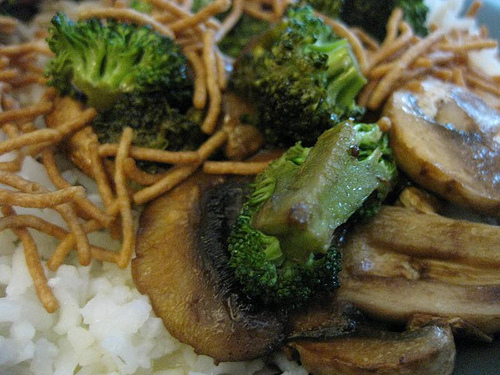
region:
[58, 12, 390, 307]
Broccoli florets on rice.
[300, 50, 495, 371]
Sauteed mushrooms on rice.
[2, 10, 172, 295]
Crispy chow mein noodles on rice.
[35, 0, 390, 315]
Broccoli florets are green.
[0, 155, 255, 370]
Stir fry rice is white.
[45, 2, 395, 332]
Broccoli is cooked al dente.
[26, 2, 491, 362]
Mushrooms mixed with broccoli.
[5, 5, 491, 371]
Stir fry vegetables and rice.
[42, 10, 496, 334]
Broccoli and mushrooms stir fry.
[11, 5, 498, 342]
Stir fry is cooked.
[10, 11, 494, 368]
Cooked meal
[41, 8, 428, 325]
Three pieces of broccoli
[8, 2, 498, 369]
Salted vegetables on top of cooked rice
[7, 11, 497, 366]
Cooked rice served at the botton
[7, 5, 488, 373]
Rice is bleached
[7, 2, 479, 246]
Noodles on top od rice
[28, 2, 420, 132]
Pieces of broccoli on noodles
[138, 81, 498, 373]
Cooked pieces of zucchini.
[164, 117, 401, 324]
One piece of broccoli over zucchini.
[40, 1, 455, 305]
Floretes of broccoli are on top of meal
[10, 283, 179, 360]
fluffy grains of cooked white rice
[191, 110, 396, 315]
piece of cut broccoli with stem and florets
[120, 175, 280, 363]
tan and black piece of curved mushroom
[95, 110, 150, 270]
curving of short piece of fried noodle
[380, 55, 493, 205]
glistening of cut surface of mushroom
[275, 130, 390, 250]
moisture on the cooked broccoli stem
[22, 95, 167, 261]
jumble of fried noodles topping an entree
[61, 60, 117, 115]
cut underside of a broccoli stem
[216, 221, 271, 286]
round pin-like heads of broccoli floret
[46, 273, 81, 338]
curled grain of rice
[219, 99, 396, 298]
a piece of broccoli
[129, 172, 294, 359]
a saute'd mushroom on a plate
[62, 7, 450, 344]
a plate of cooked food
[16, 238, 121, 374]
a portion of white rice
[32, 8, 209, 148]
green broccoli on a plate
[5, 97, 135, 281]
crunchy topping on dish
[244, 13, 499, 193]
broccoli with mushrooms and rice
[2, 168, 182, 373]
crunchy topping with white rice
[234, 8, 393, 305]
green tender cooked broccoli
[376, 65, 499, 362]
plate with cooked mushrooms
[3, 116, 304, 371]
white rice under veggies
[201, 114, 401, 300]
cooked green broccoli on top of dish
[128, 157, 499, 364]
large brown mushroom on rice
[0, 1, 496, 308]
small brown noodles over rice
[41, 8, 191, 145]
small green broccoli on top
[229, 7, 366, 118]
small green broccoli on top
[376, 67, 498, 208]
brown mushroom near broccoli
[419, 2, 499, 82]
rice in background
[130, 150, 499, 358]
mushroom under cooked broccoli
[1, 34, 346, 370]
cooked white rice provides bed for veggies